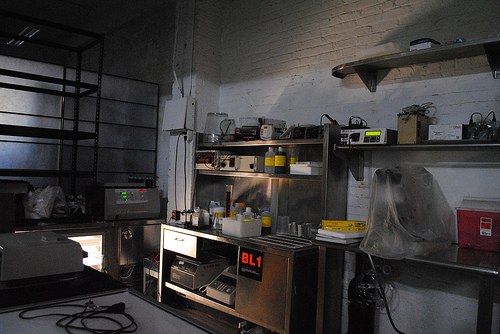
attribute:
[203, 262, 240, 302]
cash register — tan color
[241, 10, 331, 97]
brick wall — painted, white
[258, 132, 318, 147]
shelf — metal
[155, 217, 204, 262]
drawer — metal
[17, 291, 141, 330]
cable — very long 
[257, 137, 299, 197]
labels — yellow 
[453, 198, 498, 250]
cooler — red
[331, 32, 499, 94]
high shelf — high  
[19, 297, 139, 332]
cable — black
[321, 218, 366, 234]
yellow box — aluminmum paper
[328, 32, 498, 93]
shelf — silver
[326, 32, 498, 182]
shelves — two different 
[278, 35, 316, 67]
ground — black, red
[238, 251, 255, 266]
capital letters — Two capital, orange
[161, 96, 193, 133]
box — white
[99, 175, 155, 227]
machine — strange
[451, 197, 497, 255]
disposal bin — medical waste disposal 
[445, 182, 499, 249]
box — red, mysterious o_0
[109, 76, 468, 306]
machine — cover , plastic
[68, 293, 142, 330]
cord — black, unconnected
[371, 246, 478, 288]
table — stainless steel metal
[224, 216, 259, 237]
item — many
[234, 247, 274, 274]
sign — BL1"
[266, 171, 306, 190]
box — white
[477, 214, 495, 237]
sticker — caution warning